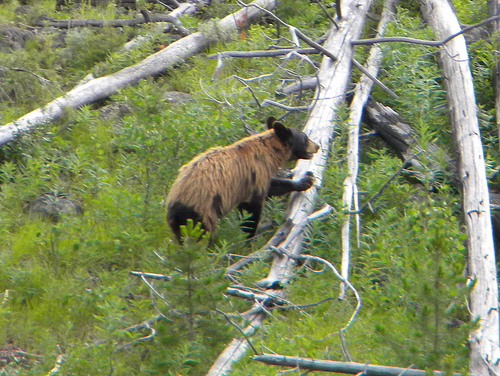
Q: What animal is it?
A: A bear.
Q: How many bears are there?
A: One.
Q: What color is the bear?
A: Brown.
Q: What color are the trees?
A: White.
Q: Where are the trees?
A: Around bear.